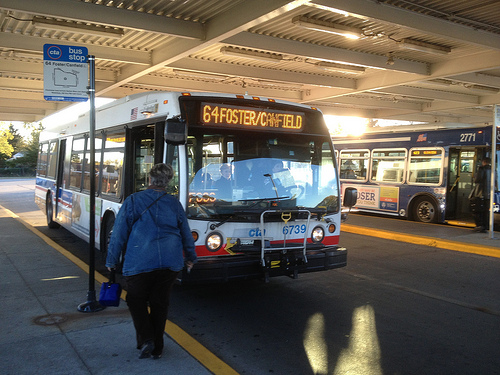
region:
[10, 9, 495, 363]
Photo taken during the day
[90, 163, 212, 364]
Woman at the bus stop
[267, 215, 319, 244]
Bus #6739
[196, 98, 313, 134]
Bus heading to Foster/Canfield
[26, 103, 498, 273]
Two buses under the roof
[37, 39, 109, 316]
Bus stop sign on sidewalk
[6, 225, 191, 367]
Sidewalk made of concrete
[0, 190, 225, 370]
The curb is yellow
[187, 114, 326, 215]
Large windshield on the bus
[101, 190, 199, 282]
Blue coat on the woman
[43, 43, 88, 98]
blue and white bus stop sign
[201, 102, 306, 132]
bus route on front of public bus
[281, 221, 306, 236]
blue bus ID number on front of bus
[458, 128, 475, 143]
white bus number on side of bus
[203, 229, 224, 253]
round headlight on front of bus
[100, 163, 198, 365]
woman walking next to bus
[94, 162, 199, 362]
woman wearing blue jacket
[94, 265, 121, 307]
blue lunch bag in hand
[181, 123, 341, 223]
windshield on public bus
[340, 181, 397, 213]
advertisement on side of bus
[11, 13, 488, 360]
photograph taken at a bus station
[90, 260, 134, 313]
blue and black lunch bag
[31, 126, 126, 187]
row of passenger windows on bus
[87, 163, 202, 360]
woman walking towards bus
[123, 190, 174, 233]
black strap around woman's chest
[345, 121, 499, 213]
blue passenger bus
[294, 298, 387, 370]
sun light shining on road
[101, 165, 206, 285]
woman wearing a jean jacket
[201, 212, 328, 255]
two front headlights on bus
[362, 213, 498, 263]
curb painted yellow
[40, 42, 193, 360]
Woman in a blue jacket at a bus stop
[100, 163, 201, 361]
Woman carrying a blue lunch bag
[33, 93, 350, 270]
Bus going to Foster/Canfield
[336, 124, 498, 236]
Blue bus number 2771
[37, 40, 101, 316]
Blue CTA bus stop sign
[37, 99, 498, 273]
Two buses at a bus stop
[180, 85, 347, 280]
Bus number 6739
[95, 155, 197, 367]
Woman walking to bus in black pants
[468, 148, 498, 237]
Man in black pants getting on bus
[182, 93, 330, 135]
sign on bus saying 64Foster/Canfield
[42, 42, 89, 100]
Blue and white bus stop sign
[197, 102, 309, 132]
Digital bus route sign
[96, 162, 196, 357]
Passenger walking towards bus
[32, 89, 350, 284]
Parked public transit bus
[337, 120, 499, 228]
Blue public transit bus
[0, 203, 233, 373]
Cement curb with yellow line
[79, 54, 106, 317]
Metal bus stop sign pole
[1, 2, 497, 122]
Ceiling of bus stop zone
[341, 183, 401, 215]
Advertisement sign on bus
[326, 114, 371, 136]
Sun shining through opening